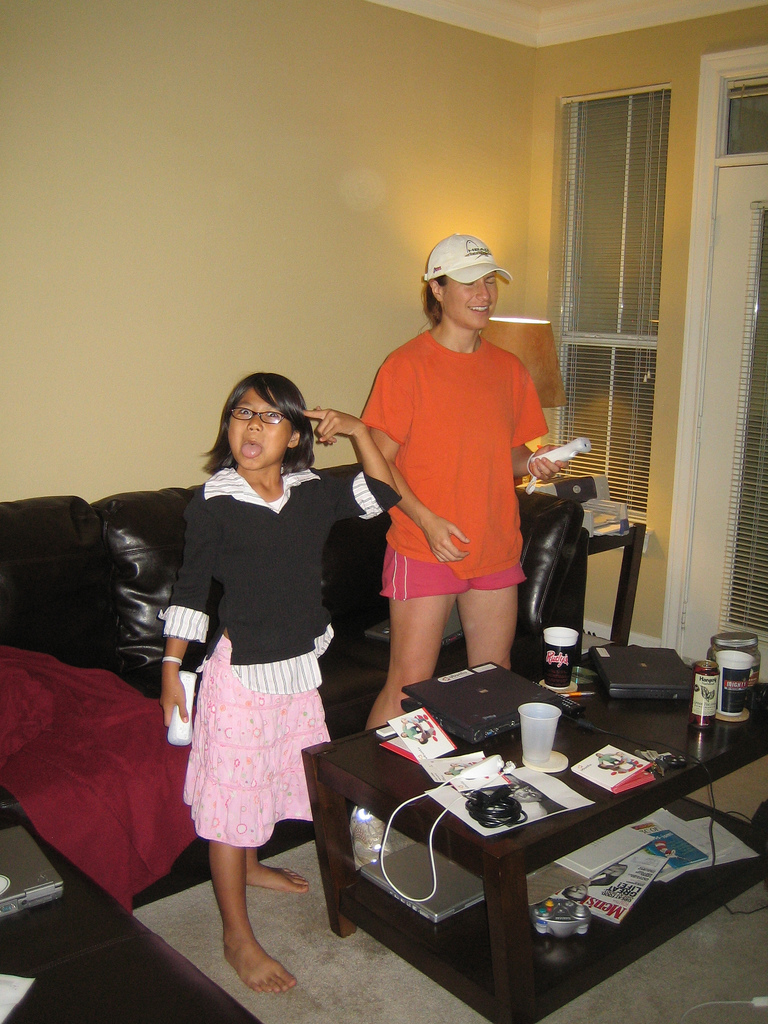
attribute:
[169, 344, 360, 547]
girl — young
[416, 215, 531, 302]
hat — white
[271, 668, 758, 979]
coffee table — wooden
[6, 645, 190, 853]
blanket — red